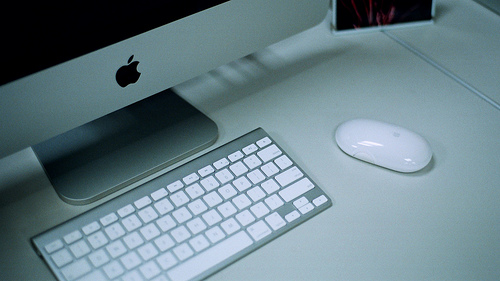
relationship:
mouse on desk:
[334, 118, 433, 173] [0, 1, 499, 280]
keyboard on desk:
[31, 127, 332, 280] [0, 1, 499, 280]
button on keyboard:
[256, 135, 272, 147] [31, 127, 332, 280]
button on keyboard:
[274, 166, 305, 188] [31, 127, 332, 280]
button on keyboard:
[215, 167, 234, 184] [31, 127, 332, 280]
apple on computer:
[114, 54, 142, 88] [0, 1, 331, 206]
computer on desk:
[0, 1, 331, 206] [0, 1, 499, 280]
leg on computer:
[32, 87, 219, 207] [0, 1, 331, 206]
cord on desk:
[381, 28, 499, 109] [0, 1, 499, 280]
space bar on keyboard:
[166, 232, 253, 280] [31, 127, 332, 280]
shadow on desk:
[2, 43, 351, 207] [0, 1, 499, 280]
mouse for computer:
[334, 118, 433, 173] [0, 1, 331, 206]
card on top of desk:
[333, 0, 438, 34] [0, 1, 499, 280]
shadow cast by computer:
[2, 43, 351, 207] [0, 1, 331, 206]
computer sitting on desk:
[0, 1, 331, 206] [0, 1, 499, 280]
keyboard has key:
[31, 127, 332, 280] [189, 199, 208, 213]